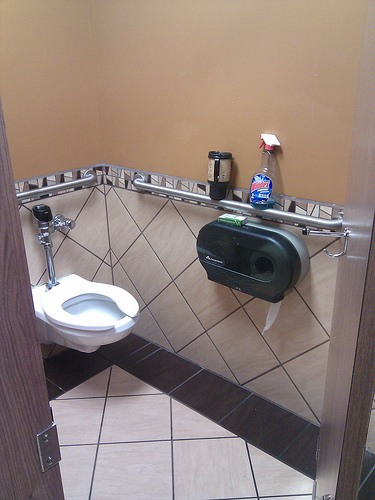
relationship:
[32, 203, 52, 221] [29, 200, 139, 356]
button for flush toilet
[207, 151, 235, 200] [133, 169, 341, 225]
cup resting on hand rail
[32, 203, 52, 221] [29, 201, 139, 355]
button on toilet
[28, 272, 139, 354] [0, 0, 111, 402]
toilet attached to wall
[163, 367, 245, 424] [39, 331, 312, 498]
tile on floor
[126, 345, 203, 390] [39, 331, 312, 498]
tile on floor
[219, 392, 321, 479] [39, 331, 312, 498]
tile on floor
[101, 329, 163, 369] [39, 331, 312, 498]
tile on floor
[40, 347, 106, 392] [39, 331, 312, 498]
tile on floor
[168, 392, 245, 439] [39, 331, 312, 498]
tile on floor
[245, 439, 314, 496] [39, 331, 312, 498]
tile on floor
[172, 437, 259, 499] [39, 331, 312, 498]
tile on floor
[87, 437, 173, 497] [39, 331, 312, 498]
tile on floor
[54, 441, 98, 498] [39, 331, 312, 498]
tile on floor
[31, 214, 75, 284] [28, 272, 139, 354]
pipe connected to toilet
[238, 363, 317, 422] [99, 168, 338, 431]
tile on wall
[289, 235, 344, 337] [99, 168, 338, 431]
tile on wall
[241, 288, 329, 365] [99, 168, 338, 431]
tile on wall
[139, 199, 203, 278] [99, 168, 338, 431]
tile on wall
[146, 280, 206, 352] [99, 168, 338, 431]
tile on wall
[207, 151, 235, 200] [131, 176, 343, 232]
cup on bar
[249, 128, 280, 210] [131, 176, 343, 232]
cleaner on bar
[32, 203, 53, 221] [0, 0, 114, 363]
button on wall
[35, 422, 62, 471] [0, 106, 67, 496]
door hinge on door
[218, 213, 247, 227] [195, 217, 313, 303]
pack on toilet-paper holder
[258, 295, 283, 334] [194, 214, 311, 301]
toilet paper hanging from dispenser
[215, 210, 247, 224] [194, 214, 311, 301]
pack on dispenser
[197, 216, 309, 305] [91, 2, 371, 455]
dispenser on wall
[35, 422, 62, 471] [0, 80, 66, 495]
door hinge on wall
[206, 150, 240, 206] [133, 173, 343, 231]
cup on hand rail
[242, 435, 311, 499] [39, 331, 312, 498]
tile on floor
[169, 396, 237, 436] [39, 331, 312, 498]
tile on floor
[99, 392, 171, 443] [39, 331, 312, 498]
tile on floor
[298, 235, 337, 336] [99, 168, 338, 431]
tile on wall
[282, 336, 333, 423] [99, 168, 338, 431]
tile on wall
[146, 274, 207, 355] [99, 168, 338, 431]
tile on wall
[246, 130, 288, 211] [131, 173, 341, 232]
bottle on rail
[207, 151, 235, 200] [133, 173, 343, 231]
cup on hand rail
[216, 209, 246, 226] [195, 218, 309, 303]
carton on dispenser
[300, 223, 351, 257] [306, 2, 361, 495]
rack on door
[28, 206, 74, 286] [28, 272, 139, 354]
pipe for toilet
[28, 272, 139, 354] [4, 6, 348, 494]
toilet in stall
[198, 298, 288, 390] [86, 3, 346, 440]
tile on wall